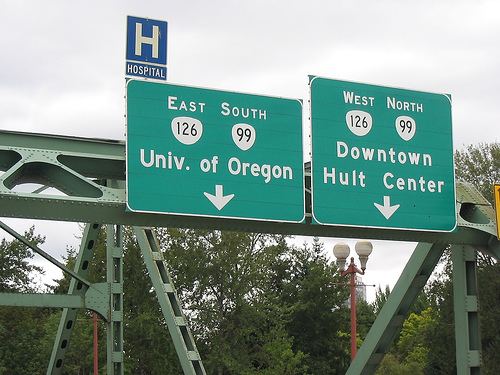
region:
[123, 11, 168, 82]
blue and white hospital sign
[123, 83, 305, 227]
green sign on the left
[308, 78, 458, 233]
green sign on the right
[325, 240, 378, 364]
red lamp post with two white globes ontop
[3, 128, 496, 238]
green bridge where signs are fastened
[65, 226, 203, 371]
three green bridge supports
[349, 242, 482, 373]
two green bridge supports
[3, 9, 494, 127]
blue sky in top of picture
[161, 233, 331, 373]
green trees behind bridge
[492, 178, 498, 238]
edge of a yellow sign on the right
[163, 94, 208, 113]
the word east written on a road sign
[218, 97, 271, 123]
the word south written on a road sign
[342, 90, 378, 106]
the word west written on a road sign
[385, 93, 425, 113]
the word north written on a road sign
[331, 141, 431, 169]
the word downtown written on a road sign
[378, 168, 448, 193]
the word center written on a road sign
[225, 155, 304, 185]
the word oregon written on a road sign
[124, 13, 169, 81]
A hospital road sign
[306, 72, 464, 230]
a green road side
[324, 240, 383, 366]
a lamppost on the road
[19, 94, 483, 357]
metal supports of bridge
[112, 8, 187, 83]
blue and white sign indicates hospital is nearby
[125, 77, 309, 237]
green and white metal sign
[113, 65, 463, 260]
two green and white signs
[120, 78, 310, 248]
sign indicates university of oregon is straight ahead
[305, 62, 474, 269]
sign indicates downtown is straight ahead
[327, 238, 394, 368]
decorative street lamp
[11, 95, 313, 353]
trees with green leaves and cloudy sky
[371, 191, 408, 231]
white arrow on green sign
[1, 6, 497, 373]
Green signs on the highway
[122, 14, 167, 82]
Hospital sign on top of highway sign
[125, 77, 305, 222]
Univ. of Oregon lane to exit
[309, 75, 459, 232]
Downtown Hult Center highway lane exit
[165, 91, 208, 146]
Lane to exit highway East 126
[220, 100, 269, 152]
South 99 lane exit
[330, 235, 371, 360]
Red light pole with two lamps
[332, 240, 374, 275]
Two lamps on a light pole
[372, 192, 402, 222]
Arrow to show lane exit to North 99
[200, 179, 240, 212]
Arrow exit lane to Univ. of Oregon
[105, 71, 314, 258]
the letter e on a interstate sign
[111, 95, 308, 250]
the letter a on a interstate sign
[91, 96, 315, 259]
the letter s on a interstate sign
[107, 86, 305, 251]
the letter t on a interstate sign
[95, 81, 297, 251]
the letter o on a interstate sign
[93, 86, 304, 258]
the letter u on a interstate sign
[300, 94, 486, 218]
the letter h on a interstate sign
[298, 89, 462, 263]
the letter l on a interstate sign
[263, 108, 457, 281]
the letter c on a interstate sign